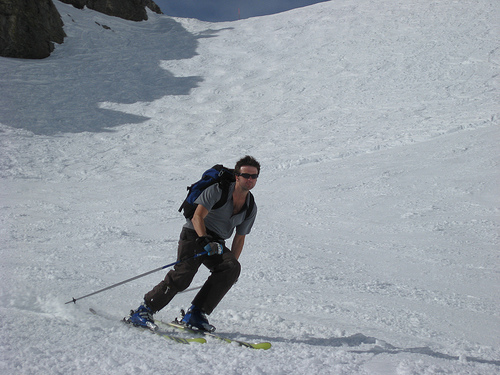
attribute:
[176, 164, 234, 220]
back pack — large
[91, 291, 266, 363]
snow ski — yellow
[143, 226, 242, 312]
pants — grey, winter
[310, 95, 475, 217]
snow — white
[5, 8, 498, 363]
snow slope — snowy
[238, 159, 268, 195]
sun glasses — dark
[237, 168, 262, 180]
goggles — black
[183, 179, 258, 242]
pullover — short, sleeve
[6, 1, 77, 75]
trees — green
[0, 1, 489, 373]
slope — snowy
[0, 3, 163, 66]
pine trees — green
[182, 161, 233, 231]
backpack — blue